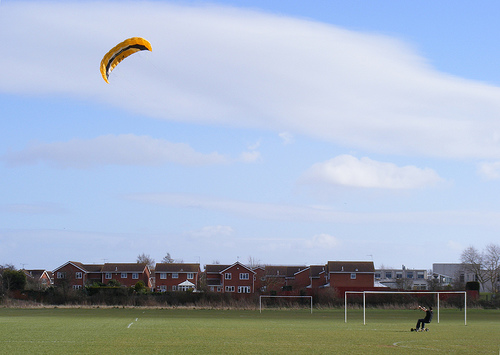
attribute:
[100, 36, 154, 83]
kite — yellow, black, flying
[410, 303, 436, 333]
man — leaned, chest up, black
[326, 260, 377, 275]
roof — small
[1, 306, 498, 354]
field — green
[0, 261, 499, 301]
houses — brick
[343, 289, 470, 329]
poles — white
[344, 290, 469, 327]
bars — white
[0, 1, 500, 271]
sky — cloudy, blue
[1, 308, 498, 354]
grass — green, soccer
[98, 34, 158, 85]
sail — paragliding, yellow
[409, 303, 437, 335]
guy — parasailing, strapped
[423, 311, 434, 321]
top — black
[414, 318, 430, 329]
pants — black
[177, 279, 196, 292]
gazebo — white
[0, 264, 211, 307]
trees — barren, row, bare, leaveless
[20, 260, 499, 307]
residences — row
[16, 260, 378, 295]
building — brick, red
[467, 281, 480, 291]
opening — black